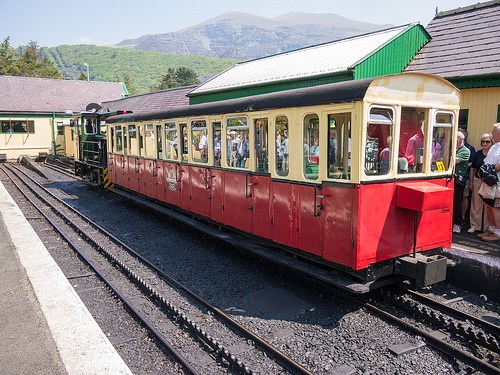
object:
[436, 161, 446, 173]
sign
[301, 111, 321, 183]
window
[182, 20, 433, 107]
green building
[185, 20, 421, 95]
white roof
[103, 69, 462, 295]
train car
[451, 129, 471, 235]
man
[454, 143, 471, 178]
shirt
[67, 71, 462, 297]
train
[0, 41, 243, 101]
mountain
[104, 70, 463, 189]
top